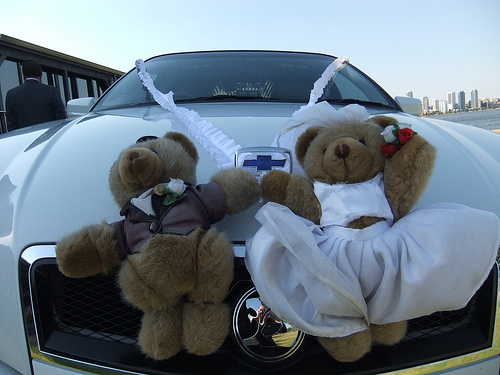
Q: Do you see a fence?
A: No, there are no fences.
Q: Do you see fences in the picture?
A: No, there are no fences.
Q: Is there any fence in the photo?
A: No, there are no fences.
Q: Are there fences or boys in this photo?
A: No, there are no fences or boys.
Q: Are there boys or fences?
A: No, there are no fences or boys.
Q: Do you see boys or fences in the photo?
A: No, there are no fences or boys.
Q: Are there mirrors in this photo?
A: Yes, there is a mirror.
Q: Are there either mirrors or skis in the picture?
A: Yes, there is a mirror.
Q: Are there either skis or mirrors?
A: Yes, there is a mirror.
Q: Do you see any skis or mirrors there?
A: Yes, there is a mirror.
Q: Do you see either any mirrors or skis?
A: Yes, there is a mirror.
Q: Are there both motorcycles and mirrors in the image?
A: No, there is a mirror but no motorcycles.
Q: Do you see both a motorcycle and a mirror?
A: No, there is a mirror but no motorcycles.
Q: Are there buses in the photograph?
A: No, there are no buses.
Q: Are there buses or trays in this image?
A: No, there are no buses or trays.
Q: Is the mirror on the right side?
A: Yes, the mirror is on the right of the image.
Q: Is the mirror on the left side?
A: No, the mirror is on the right of the image.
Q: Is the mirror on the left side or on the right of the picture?
A: The mirror is on the right of the image.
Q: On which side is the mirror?
A: The mirror is on the right of the image.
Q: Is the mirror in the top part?
A: Yes, the mirror is in the top of the image.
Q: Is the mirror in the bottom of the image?
A: No, the mirror is in the top of the image.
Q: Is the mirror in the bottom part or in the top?
A: The mirror is in the top of the image.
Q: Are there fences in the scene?
A: No, there are no fences.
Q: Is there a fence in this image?
A: No, there are no fences.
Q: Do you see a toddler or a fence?
A: No, there are no fences or toddlers.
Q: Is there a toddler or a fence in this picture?
A: No, there are no fences or toddlers.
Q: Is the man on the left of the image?
A: Yes, the man is on the left of the image.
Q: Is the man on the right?
A: No, the man is on the left of the image.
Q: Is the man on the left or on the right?
A: The man is on the left of the image.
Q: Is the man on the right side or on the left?
A: The man is on the left of the image.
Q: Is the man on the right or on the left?
A: The man is on the left of the image.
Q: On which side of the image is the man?
A: The man is on the left of the image.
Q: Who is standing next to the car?
A: The man is standing next to the car.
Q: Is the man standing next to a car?
A: Yes, the man is standing next to a car.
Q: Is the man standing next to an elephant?
A: No, the man is standing next to a car.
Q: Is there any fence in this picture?
A: No, there are no fences.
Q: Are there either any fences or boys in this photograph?
A: No, there are no fences or boys.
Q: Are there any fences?
A: No, there are no fences.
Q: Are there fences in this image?
A: No, there are no fences.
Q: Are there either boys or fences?
A: No, there are no fences or boys.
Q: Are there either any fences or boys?
A: No, there are no fences or boys.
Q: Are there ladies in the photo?
A: No, there are no ladies.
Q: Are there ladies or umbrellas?
A: No, there are no ladies or umbrellas.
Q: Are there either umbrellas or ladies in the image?
A: No, there are no ladies or umbrellas.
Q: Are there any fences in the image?
A: No, there are no fences.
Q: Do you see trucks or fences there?
A: No, there are no fences or trucks.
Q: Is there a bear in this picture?
A: Yes, there is a bear.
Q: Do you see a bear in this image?
A: Yes, there is a bear.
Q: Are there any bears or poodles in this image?
A: Yes, there is a bear.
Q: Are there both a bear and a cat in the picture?
A: No, there is a bear but no cats.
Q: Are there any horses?
A: No, there are no horses.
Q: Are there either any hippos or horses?
A: No, there are no horses or hippos.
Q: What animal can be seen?
A: The animal is a bear.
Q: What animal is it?
A: The animal is a bear.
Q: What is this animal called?
A: This is a bear.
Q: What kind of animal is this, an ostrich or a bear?
A: This is a bear.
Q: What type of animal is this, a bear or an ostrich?
A: This is a bear.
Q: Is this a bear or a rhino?
A: This is a bear.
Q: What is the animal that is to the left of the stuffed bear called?
A: The animal is a bear.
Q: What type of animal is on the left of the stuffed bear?
A: The animal is a bear.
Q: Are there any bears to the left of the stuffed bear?
A: Yes, there is a bear to the left of the stuffed bear.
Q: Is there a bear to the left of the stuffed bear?
A: Yes, there is a bear to the left of the stuffed bear.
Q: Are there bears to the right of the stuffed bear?
A: No, the bear is to the left of the stuffed bear.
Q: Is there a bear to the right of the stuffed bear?
A: No, the bear is to the left of the stuffed bear.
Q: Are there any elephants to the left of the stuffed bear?
A: No, there is a bear to the left of the stuffed bear.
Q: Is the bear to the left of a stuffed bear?
A: Yes, the bear is to the left of a stuffed bear.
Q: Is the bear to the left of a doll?
A: No, the bear is to the left of a stuffed bear.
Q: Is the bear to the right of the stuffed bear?
A: No, the bear is to the left of the stuffed bear.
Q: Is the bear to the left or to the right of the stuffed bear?
A: The bear is to the left of the stuffed bear.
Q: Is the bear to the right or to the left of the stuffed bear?
A: The bear is to the left of the stuffed bear.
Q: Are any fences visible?
A: No, there are no fences.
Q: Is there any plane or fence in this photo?
A: No, there are no fences or airplanes.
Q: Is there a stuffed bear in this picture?
A: Yes, there is a stuffed bear.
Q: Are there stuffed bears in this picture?
A: Yes, there is a stuffed bear.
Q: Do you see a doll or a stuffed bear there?
A: Yes, there is a stuffed bear.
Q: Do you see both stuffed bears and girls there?
A: No, there is a stuffed bear but no girls.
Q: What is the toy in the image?
A: The toy is a stuffed bear.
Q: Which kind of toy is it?
A: The toy is a stuffed bear.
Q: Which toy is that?
A: This is a stuffed bear.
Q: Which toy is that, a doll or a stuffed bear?
A: This is a stuffed bear.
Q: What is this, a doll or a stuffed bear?
A: This is a stuffed bear.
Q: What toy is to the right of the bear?
A: The toy is a stuffed bear.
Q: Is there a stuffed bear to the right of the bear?
A: Yes, there is a stuffed bear to the right of the bear.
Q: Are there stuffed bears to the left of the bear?
A: No, the stuffed bear is to the right of the bear.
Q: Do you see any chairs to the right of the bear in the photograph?
A: No, there is a stuffed bear to the right of the bear.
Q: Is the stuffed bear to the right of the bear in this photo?
A: Yes, the stuffed bear is to the right of the bear.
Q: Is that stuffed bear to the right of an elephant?
A: No, the stuffed bear is to the right of the bear.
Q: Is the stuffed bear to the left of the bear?
A: No, the stuffed bear is to the right of the bear.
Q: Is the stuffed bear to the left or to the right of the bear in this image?
A: The stuffed bear is to the right of the bear.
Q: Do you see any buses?
A: No, there are no buses.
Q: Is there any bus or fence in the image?
A: No, there are no buses or fences.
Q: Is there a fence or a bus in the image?
A: No, there are no buses or fences.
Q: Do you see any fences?
A: No, there are no fences.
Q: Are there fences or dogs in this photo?
A: No, there are no fences or dogs.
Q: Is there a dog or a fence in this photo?
A: No, there are no fences or dogs.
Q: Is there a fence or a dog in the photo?
A: No, there are no fences or dogs.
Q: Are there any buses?
A: No, there are no buses.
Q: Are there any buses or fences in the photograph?
A: No, there are no buses or fences.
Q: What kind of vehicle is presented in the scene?
A: The vehicle is a car.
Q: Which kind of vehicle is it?
A: The vehicle is a car.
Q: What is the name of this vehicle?
A: That is a car.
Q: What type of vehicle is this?
A: That is a car.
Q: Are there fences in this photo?
A: No, there are no fences.